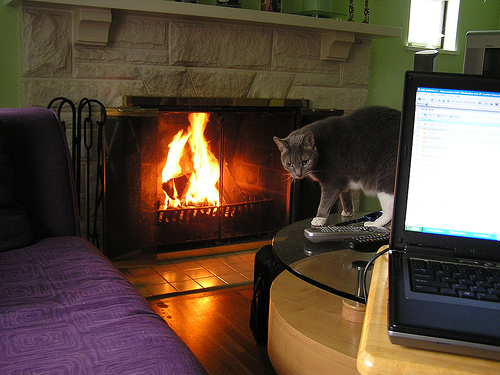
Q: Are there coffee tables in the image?
A: Yes, there is a coffee table.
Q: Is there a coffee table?
A: Yes, there is a coffee table.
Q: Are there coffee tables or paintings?
A: Yes, there is a coffee table.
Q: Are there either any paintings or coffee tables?
A: Yes, there is a coffee table.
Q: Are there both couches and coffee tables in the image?
A: Yes, there are both a coffee table and a couch.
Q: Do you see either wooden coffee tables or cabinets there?
A: Yes, there is a wood coffee table.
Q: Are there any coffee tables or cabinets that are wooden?
A: Yes, the coffee table is wooden.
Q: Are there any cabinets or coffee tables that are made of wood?
A: Yes, the coffee table is made of wood.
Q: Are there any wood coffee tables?
A: Yes, there is a wood coffee table.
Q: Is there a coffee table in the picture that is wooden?
A: Yes, there is a coffee table that is wooden.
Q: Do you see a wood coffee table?
A: Yes, there is a coffee table that is made of wood.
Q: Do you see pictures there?
A: No, there are no pictures.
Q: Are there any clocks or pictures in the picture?
A: No, there are no pictures or clocks.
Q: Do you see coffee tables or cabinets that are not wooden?
A: No, there is a coffee table but it is wooden.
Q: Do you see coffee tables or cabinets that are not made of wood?
A: No, there is a coffee table but it is made of wood.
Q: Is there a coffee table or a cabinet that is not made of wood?
A: No, there is a coffee table but it is made of wood.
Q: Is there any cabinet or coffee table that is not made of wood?
A: No, there is a coffee table but it is made of wood.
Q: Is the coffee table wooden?
A: Yes, the coffee table is wooden.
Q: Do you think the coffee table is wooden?
A: Yes, the coffee table is wooden.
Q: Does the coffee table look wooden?
A: Yes, the coffee table is wooden.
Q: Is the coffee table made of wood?
A: Yes, the coffee table is made of wood.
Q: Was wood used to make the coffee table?
A: Yes, the coffee table is made of wood.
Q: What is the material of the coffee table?
A: The coffee table is made of wood.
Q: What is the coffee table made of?
A: The coffee table is made of wood.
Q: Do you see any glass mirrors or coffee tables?
A: No, there is a coffee table but it is wooden.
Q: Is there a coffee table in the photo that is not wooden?
A: No, there is a coffee table but it is wooden.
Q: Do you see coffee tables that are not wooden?
A: No, there is a coffee table but it is wooden.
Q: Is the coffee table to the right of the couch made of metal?
A: No, the coffee table is made of wood.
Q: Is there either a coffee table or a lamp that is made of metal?
A: No, there is a coffee table but it is made of wood.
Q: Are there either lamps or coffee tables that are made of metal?
A: No, there is a coffee table but it is made of wood.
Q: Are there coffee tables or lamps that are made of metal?
A: No, there is a coffee table but it is made of wood.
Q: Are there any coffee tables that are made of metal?
A: No, there is a coffee table but it is made of wood.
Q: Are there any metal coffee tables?
A: No, there is a coffee table but it is made of wood.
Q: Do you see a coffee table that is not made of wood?
A: No, there is a coffee table but it is made of wood.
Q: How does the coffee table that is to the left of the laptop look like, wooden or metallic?
A: The coffee table is wooden.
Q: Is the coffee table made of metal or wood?
A: The coffee table is made of wood.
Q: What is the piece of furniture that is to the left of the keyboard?
A: The piece of furniture is a coffee table.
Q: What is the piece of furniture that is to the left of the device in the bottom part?
A: The piece of furniture is a coffee table.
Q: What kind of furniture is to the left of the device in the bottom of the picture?
A: The piece of furniture is a coffee table.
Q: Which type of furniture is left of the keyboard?
A: The piece of furniture is a coffee table.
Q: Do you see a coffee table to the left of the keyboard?
A: Yes, there is a coffee table to the left of the keyboard.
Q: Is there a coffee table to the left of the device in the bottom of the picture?
A: Yes, there is a coffee table to the left of the keyboard.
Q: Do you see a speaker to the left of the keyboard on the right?
A: No, there is a coffee table to the left of the keyboard.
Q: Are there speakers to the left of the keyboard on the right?
A: No, there is a coffee table to the left of the keyboard.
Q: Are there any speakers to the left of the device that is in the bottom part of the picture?
A: No, there is a coffee table to the left of the keyboard.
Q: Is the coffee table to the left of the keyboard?
A: Yes, the coffee table is to the left of the keyboard.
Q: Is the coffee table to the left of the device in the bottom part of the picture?
A: Yes, the coffee table is to the left of the keyboard.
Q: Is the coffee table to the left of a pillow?
A: No, the coffee table is to the left of the keyboard.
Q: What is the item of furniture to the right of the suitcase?
A: The piece of furniture is a coffee table.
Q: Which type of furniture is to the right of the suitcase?
A: The piece of furniture is a coffee table.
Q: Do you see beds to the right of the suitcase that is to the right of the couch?
A: No, there is a coffee table to the right of the suitcase.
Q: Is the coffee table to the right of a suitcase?
A: Yes, the coffee table is to the right of a suitcase.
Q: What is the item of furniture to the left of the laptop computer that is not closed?
A: The piece of furniture is a coffee table.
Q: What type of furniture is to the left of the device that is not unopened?
A: The piece of furniture is a coffee table.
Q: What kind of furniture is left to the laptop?
A: The piece of furniture is a coffee table.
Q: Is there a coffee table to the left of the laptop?
A: Yes, there is a coffee table to the left of the laptop.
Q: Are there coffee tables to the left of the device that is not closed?
A: Yes, there is a coffee table to the left of the laptop.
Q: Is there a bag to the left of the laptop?
A: No, there is a coffee table to the left of the laptop.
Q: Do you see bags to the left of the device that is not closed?
A: No, there is a coffee table to the left of the laptop.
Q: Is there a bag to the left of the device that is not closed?
A: No, there is a coffee table to the left of the laptop.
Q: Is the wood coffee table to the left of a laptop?
A: Yes, the coffee table is to the left of a laptop.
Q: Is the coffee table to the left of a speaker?
A: No, the coffee table is to the left of a laptop.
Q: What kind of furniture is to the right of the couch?
A: The piece of furniture is a coffee table.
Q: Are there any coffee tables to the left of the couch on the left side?
A: No, the coffee table is to the right of the couch.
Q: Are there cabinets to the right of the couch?
A: No, there is a coffee table to the right of the couch.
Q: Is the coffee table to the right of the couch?
A: Yes, the coffee table is to the right of the couch.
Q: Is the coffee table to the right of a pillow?
A: No, the coffee table is to the right of the couch.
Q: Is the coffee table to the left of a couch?
A: No, the coffee table is to the right of a couch.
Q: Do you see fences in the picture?
A: No, there are no fences.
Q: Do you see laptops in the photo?
A: Yes, there is a laptop.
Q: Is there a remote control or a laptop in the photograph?
A: Yes, there is a laptop.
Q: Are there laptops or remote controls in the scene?
A: Yes, there is a laptop.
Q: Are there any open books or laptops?
A: Yes, there is an open laptop.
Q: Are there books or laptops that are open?
A: Yes, the laptop is open.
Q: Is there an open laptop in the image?
A: Yes, there is an open laptop.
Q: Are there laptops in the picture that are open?
A: Yes, there is a laptop that is open.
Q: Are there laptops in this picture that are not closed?
A: Yes, there is a open laptop.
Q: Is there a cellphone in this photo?
A: No, there are no cell phones.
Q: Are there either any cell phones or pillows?
A: No, there are no cell phones or pillows.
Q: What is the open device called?
A: The device is a laptop.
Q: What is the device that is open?
A: The device is a laptop.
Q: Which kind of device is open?
A: The device is a laptop.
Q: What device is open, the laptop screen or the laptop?
A: The laptop is open.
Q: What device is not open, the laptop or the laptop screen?
A: The screen is not open.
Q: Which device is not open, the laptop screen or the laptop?
A: The screen is not open.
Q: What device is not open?
A: The device is a screen.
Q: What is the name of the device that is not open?
A: The device is a screen.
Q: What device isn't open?
A: The device is a screen.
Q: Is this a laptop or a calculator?
A: This is a laptop.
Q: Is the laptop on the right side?
A: Yes, the laptop is on the right of the image.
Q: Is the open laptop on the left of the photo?
A: No, the laptop is on the right of the image.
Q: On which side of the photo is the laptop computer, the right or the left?
A: The laptop computer is on the right of the image.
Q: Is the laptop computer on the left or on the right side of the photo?
A: The laptop computer is on the right of the image.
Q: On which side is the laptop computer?
A: The laptop computer is on the right of the image.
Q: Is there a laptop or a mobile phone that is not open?
A: No, there is a laptop but it is open.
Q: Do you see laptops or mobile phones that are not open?
A: No, there is a laptop but it is open.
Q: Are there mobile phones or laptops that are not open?
A: No, there is a laptop but it is open.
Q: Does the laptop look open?
A: Yes, the laptop is open.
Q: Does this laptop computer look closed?
A: No, the laptop computer is open.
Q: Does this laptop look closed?
A: No, the laptop is open.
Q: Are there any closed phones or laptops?
A: No, there is a laptop but it is open.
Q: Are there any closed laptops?
A: No, there is a laptop but it is open.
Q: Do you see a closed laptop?
A: No, there is a laptop but it is open.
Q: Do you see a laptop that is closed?
A: No, there is a laptop but it is open.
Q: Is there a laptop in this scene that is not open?
A: No, there is a laptop but it is open.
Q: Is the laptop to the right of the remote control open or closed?
A: The laptop is open.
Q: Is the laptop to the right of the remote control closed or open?
A: The laptop is open.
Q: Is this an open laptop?
A: Yes, this is an open laptop.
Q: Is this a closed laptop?
A: No, this is an open laptop.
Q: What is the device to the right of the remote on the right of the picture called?
A: The device is a laptop.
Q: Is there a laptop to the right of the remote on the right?
A: Yes, there is a laptop to the right of the remote.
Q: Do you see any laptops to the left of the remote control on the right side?
A: No, the laptop is to the right of the remote.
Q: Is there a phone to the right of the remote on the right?
A: No, there is a laptop to the right of the remote control.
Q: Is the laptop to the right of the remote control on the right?
A: Yes, the laptop is to the right of the remote.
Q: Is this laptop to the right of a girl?
A: No, the laptop is to the right of the remote.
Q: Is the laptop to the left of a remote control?
A: No, the laptop is to the right of a remote control.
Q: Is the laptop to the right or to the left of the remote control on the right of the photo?
A: The laptop is to the right of the remote control.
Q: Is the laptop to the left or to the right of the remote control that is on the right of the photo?
A: The laptop is to the right of the remote control.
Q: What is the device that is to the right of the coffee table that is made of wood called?
A: The device is a laptop.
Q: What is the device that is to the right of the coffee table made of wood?
A: The device is a laptop.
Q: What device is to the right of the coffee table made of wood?
A: The device is a laptop.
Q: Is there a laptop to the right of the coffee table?
A: Yes, there is a laptop to the right of the coffee table.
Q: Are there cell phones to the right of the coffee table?
A: No, there is a laptop to the right of the coffee table.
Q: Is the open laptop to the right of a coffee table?
A: Yes, the laptop is to the right of a coffee table.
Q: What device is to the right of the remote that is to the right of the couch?
A: The device is a laptop.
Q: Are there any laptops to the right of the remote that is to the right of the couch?
A: Yes, there is a laptop to the right of the remote.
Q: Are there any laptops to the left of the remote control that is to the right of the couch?
A: No, the laptop is to the right of the remote control.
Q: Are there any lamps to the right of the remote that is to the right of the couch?
A: No, there is a laptop to the right of the remote.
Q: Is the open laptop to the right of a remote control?
A: Yes, the laptop is to the right of a remote control.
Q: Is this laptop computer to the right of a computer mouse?
A: No, the laptop computer is to the right of a remote control.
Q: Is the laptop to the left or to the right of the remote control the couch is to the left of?
A: The laptop is to the right of the remote control.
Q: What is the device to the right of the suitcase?
A: The device is a laptop.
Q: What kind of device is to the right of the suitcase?
A: The device is a laptop.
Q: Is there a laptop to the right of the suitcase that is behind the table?
A: Yes, there is a laptop to the right of the suitcase.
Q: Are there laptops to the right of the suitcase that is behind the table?
A: Yes, there is a laptop to the right of the suitcase.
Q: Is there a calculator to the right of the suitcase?
A: No, there is a laptop to the right of the suitcase.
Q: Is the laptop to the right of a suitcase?
A: Yes, the laptop is to the right of a suitcase.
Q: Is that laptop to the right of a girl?
A: No, the laptop is to the right of a suitcase.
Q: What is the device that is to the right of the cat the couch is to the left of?
A: The device is a laptop.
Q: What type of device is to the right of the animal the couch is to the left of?
A: The device is a laptop.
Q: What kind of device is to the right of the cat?
A: The device is a laptop.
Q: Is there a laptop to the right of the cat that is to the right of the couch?
A: Yes, there is a laptop to the right of the cat.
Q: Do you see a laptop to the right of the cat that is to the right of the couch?
A: Yes, there is a laptop to the right of the cat.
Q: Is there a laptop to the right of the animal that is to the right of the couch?
A: Yes, there is a laptop to the right of the cat.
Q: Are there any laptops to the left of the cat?
A: No, the laptop is to the right of the cat.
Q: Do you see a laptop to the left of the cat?
A: No, the laptop is to the right of the cat.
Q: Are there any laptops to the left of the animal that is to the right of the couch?
A: No, the laptop is to the right of the cat.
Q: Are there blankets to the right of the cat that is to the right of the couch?
A: No, there is a laptop to the right of the cat.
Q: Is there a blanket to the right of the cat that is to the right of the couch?
A: No, there is a laptop to the right of the cat.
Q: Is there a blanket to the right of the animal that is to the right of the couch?
A: No, there is a laptop to the right of the cat.